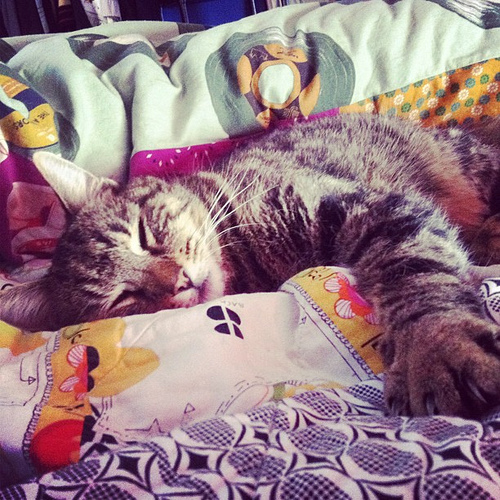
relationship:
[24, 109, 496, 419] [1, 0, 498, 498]
cat on bed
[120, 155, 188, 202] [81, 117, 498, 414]
ear on cat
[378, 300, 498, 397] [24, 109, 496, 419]
paw on cat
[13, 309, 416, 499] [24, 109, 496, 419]
blanket on cat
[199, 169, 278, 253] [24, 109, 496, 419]
whiskers on cat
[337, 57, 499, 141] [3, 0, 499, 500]
stripe on blanket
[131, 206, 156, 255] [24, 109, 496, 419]
eye on cat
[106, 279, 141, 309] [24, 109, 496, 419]
eye on cat